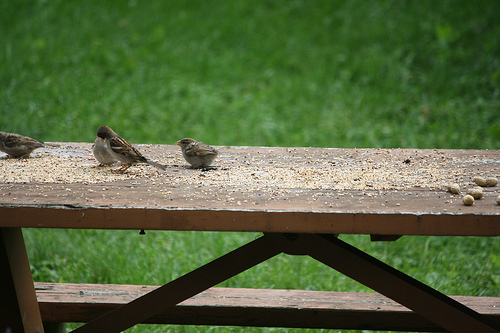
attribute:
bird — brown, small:
[177, 139, 218, 171]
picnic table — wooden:
[0, 140, 500, 331]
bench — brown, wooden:
[30, 281, 499, 331]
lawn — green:
[1, 0, 499, 332]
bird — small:
[0, 132, 47, 160]